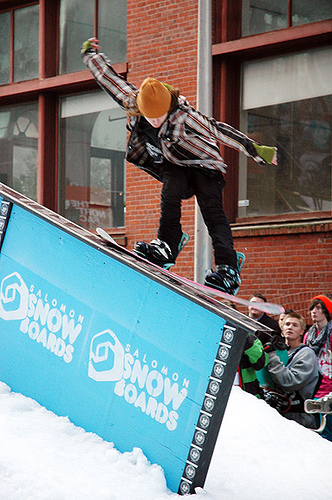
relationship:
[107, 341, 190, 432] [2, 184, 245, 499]
lettering on sign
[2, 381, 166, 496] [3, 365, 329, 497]
snow on ground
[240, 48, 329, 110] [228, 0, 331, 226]
curtains are on window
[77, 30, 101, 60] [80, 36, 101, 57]
gloves are on hand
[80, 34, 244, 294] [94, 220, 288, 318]
boy snowboarding on ramp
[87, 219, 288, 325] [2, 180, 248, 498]
snowboard on ramp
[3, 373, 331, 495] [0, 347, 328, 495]
snow on hill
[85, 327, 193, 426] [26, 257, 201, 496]
brand name in front of sign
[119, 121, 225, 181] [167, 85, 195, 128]
jacket with hood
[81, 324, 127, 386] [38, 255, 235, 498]
logo in front of sign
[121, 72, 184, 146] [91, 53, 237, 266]
head of a person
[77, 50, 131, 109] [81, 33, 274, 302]
arm of a person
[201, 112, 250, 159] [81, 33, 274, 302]
arm of a person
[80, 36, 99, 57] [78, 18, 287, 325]
hand of a person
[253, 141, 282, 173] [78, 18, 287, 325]
hand of a person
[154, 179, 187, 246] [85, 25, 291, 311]
leg of a person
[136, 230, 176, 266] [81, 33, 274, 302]
foot of a person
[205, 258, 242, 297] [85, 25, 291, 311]
foot of a person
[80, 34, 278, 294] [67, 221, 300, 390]
boy snowboarding on a ramp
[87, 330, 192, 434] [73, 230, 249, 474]
brand name on side of a snowboard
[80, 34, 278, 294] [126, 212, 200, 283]
boy wearing boot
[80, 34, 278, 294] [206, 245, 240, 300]
boy wearing boot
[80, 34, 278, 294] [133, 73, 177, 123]
boy wearing a hat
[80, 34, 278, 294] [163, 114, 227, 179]
boy wearing a shirt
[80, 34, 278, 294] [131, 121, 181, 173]
boy wearing a shirt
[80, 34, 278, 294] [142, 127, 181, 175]
boy wearing shirt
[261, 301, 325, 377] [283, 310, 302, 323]
man with hair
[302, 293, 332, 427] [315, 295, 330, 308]
kid wearing a hat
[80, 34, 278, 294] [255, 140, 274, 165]
boy wearing glove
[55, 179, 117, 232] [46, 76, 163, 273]
sign in window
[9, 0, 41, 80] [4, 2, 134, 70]
pane on top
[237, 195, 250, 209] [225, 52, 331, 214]
sticker on window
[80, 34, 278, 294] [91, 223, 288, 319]
boy on snowboard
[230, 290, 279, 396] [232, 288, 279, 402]
person wears shirt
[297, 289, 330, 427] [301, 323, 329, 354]
kid wears shirt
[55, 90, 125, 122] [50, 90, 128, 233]
blind on window